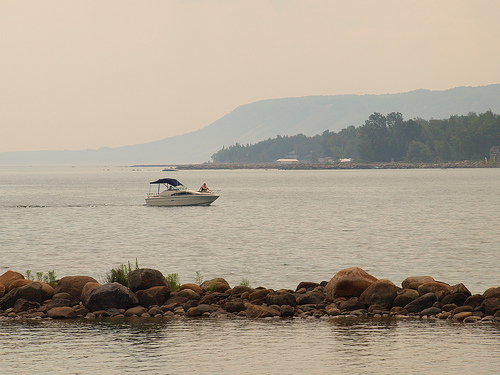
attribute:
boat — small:
[146, 174, 220, 209]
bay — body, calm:
[1, 162, 499, 297]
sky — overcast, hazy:
[2, 4, 499, 154]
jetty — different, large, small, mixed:
[1, 268, 499, 329]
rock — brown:
[325, 267, 378, 300]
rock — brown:
[180, 282, 202, 296]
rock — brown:
[82, 282, 101, 304]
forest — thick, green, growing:
[208, 110, 499, 163]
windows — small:
[173, 192, 198, 196]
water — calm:
[1, 166, 500, 374]